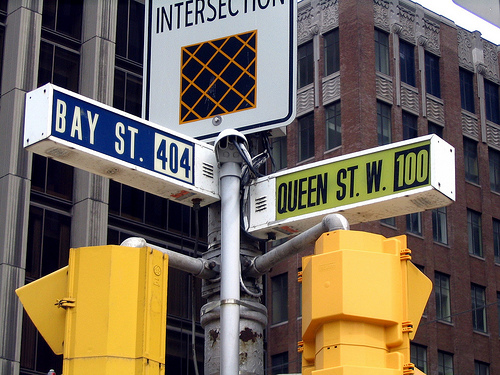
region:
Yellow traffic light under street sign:
[295, 227, 430, 374]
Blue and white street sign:
[22, 79, 218, 211]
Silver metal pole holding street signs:
[200, 128, 265, 373]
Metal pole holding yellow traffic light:
[120, 235, 216, 277]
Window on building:
[370, 20, 392, 75]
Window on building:
[395, 34, 420, 89]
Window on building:
[423, 45, 444, 100]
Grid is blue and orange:
[172, 26, 259, 124]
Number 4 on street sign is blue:
[156, 137, 166, 174]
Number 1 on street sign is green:
[395, 152, 405, 186]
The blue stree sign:
[21, 82, 221, 207]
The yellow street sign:
[237, 128, 459, 242]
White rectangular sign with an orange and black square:
[144, 0, 303, 135]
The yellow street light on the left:
[8, 228, 171, 373]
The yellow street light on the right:
[293, 222, 438, 374]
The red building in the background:
[263, 0, 499, 374]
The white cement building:
[0, 0, 209, 374]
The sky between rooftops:
[418, 0, 497, 44]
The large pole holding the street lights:
[195, 136, 269, 374]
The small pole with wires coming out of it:
[209, 126, 252, 373]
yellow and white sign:
[133, 0, 314, 147]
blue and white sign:
[13, 75, 230, 227]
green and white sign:
[226, 124, 459, 244]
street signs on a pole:
[13, 1, 494, 235]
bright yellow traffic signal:
[261, 207, 453, 374]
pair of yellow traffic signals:
[4, 213, 461, 373]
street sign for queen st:
[238, 128, 472, 236]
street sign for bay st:
[18, 60, 228, 217]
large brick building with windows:
[268, 2, 489, 373]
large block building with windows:
[1, 3, 233, 373]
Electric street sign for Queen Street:
[238, 128, 457, 236]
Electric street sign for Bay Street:
[23, 77, 220, 202]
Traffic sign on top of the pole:
[136, 3, 297, 146]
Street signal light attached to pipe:
[297, 226, 437, 373]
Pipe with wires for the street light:
[252, 213, 359, 288]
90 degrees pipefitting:
[318, 208, 355, 233]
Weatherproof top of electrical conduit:
[213, 127, 254, 171]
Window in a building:
[461, 198, 488, 264]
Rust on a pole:
[239, 323, 265, 349]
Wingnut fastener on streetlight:
[54, 296, 65, 312]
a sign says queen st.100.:
[255, 140, 458, 221]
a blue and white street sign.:
[30, 80, 225, 190]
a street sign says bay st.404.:
[35, 85, 210, 195]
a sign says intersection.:
[135, 0, 315, 145]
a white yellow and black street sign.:
[130, 0, 300, 140]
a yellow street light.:
[285, 255, 415, 355]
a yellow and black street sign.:
[260, 140, 445, 225]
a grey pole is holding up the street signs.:
[181, 201, 278, 371]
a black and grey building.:
[25, 180, 137, 236]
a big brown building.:
[305, 42, 481, 125]